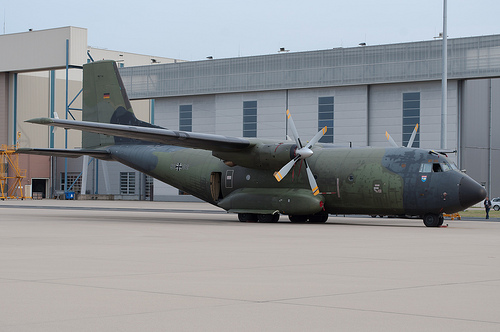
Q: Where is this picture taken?
A: Air strip.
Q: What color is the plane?
A: Green.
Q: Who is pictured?
A: No one.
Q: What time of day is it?
A: Day time.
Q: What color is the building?
A: Gray.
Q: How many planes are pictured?
A: One.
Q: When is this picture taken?
A: Before flight.